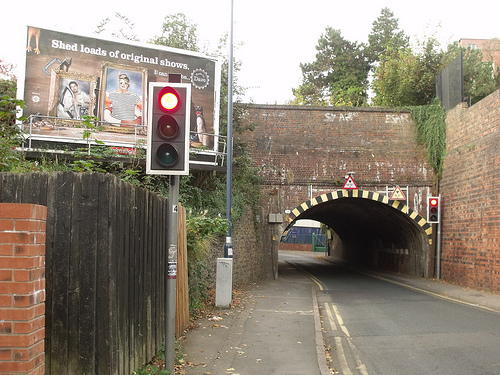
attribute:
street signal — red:
[153, 79, 187, 172]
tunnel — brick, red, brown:
[236, 126, 467, 275]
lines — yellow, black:
[281, 191, 423, 228]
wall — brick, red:
[201, 102, 498, 280]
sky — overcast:
[3, 0, 499, 96]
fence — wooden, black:
[434, 57, 480, 107]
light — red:
[162, 90, 182, 115]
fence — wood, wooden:
[9, 180, 194, 374]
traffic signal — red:
[160, 91, 178, 105]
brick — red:
[436, 116, 500, 285]